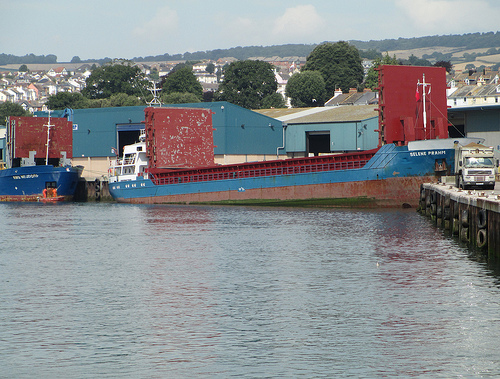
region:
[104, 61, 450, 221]
a freighter is lopsided at its mooring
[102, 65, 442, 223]
the ship is blue and white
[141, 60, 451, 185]
the ship has red decking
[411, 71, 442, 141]
a flagstaff is on the bow of the ship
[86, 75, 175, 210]
the ship is heavier on the stern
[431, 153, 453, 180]
the ship's anchor is in the bow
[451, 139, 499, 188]
a box truck is on the dock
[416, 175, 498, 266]
the dock has wooden pilings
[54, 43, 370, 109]
green trees are behind the port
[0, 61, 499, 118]
row houses are behind the port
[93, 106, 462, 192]
the ship is blue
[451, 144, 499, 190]
the truck is white in color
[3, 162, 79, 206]
the ship is blue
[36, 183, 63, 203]
the lifejacket is red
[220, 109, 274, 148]
the walls are blue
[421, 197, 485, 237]
the tires are black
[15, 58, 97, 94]
houses are in the background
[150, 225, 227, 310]
reflection is on the water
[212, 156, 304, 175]
the bars are red in color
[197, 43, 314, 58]
trees are in the background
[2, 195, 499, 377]
large body of water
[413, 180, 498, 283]
bridge over the water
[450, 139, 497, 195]
truck on a bridge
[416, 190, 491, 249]
tires on a bridge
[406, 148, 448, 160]
white words on the blue part of a boat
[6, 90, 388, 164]
blue building on the shore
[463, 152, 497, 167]
windshield on the truck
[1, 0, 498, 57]
hazy sky above the trees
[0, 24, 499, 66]
line of trees in the distance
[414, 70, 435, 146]
white mast on the bigger boat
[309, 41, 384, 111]
Large green tree in distance.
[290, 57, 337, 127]
Large green tree in distance.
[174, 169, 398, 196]
Large blue ship in water.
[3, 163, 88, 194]
Large blue boat in water.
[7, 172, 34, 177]
White writing on side of boat.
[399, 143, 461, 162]
White writing on side of boat.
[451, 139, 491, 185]
White truck on road near water.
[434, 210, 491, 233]
Black tires hanging off of wall.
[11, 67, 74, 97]
Many houses in distance.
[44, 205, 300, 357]
Water is dark in color.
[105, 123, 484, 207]
a boat in the water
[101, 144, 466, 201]
the boat trim is blue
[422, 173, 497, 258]
a bridge beside the boat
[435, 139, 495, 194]
a truck on the bridge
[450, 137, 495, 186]
the truck is white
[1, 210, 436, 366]
gentle waves on the water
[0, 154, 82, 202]
a large blue boat front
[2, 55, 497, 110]
a city behind the boats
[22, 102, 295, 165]
a large blue building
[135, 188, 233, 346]
a red reflection on the water